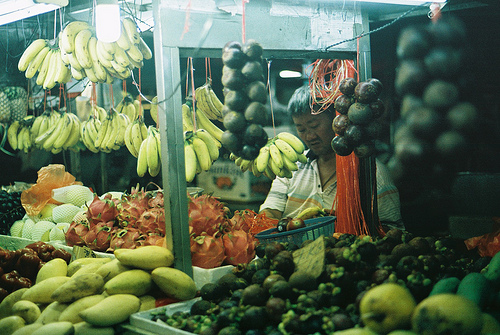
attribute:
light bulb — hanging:
[74, 4, 130, 44]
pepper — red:
[21, 257, 38, 272]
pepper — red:
[0, 276, 27, 287]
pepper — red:
[5, 250, 20, 268]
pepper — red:
[28, 242, 35, 246]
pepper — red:
[40, 247, 54, 255]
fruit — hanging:
[225, 54, 238, 69]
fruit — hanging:
[228, 100, 241, 108]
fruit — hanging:
[252, 108, 263, 120]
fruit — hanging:
[246, 61, 257, 78]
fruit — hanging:
[240, 147, 255, 155]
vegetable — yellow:
[99, 304, 131, 321]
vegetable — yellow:
[34, 282, 56, 294]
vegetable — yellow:
[129, 252, 161, 264]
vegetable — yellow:
[20, 303, 34, 313]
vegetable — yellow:
[114, 275, 149, 288]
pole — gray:
[170, 21, 180, 273]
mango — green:
[369, 298, 404, 319]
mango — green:
[424, 305, 463, 325]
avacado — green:
[329, 78, 386, 155]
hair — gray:
[292, 91, 312, 106]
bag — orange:
[475, 236, 499, 251]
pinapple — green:
[14, 101, 27, 117]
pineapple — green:
[3, 98, 11, 122]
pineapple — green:
[8, 88, 26, 95]